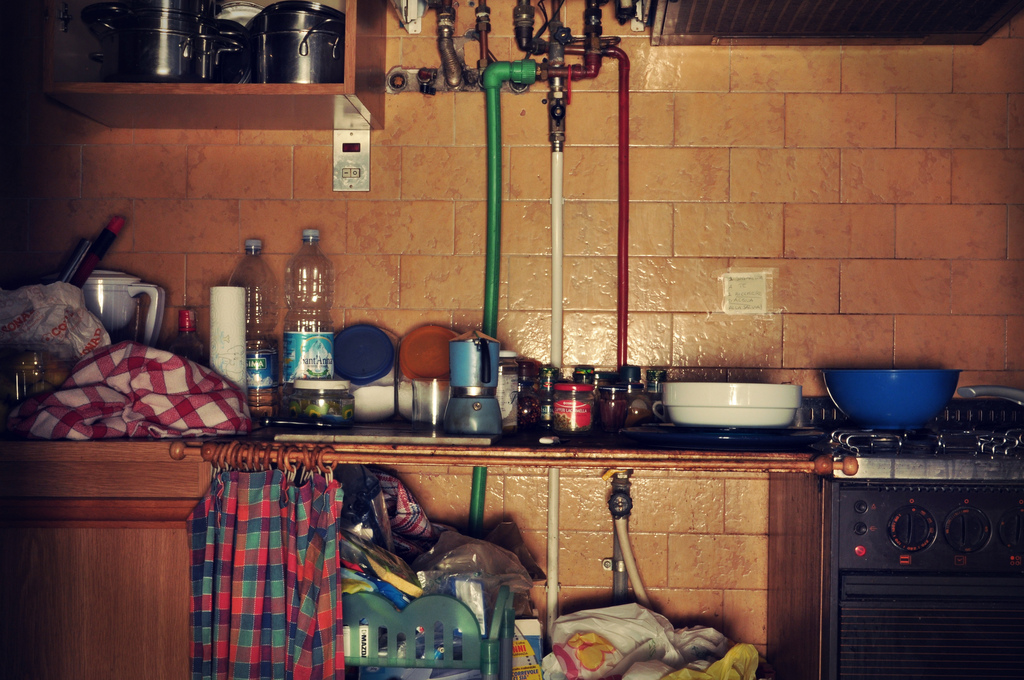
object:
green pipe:
[477, 61, 505, 338]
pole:
[167, 440, 860, 476]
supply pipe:
[616, 52, 632, 373]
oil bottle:
[277, 228, 334, 432]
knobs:
[840, 496, 1024, 566]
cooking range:
[822, 402, 1024, 679]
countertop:
[0, 438, 859, 522]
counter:
[203, 441, 860, 474]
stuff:
[339, 467, 760, 680]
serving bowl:
[821, 367, 964, 433]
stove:
[814, 409, 1024, 678]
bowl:
[662, 380, 804, 429]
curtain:
[187, 436, 343, 678]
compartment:
[340, 464, 769, 680]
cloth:
[2, 342, 260, 445]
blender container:
[82, 269, 165, 349]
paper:
[720, 272, 769, 315]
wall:
[0, 0, 1022, 398]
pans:
[20, 0, 340, 82]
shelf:
[2, 82, 342, 131]